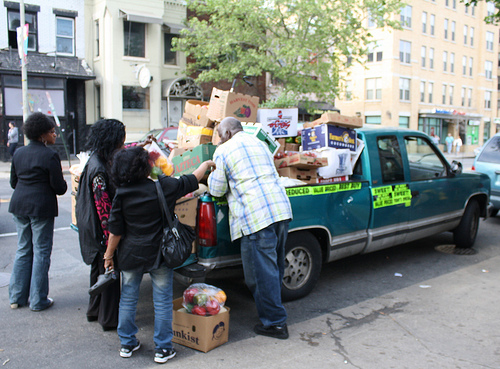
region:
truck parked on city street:
[15, 45, 486, 341]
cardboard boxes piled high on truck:
[142, 80, 357, 202]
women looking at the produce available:
[10, 100, 186, 355]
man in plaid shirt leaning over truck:
[190, 95, 310, 336]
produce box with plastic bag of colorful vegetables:
[160, 277, 235, 357]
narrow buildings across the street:
[0, 0, 330, 141]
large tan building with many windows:
[325, 10, 495, 150]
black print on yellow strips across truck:
[280, 175, 425, 207]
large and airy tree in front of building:
[161, 7, 383, 102]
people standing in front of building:
[415, 100, 483, 157]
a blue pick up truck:
[132, 97, 498, 281]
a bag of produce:
[172, 277, 238, 332]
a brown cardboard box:
[156, 293, 235, 353]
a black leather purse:
[152, 172, 207, 274]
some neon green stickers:
[369, 181, 419, 209]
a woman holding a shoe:
[91, 147, 217, 362]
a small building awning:
[159, 67, 212, 102]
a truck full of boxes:
[131, 77, 488, 217]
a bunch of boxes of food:
[163, 80, 335, 186]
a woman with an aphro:
[7, 106, 81, 322]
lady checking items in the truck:
[6, 111, 66, 311]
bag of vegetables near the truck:
[182, 282, 226, 313]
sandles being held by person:
[86, 257, 113, 294]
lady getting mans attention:
[100, 145, 217, 357]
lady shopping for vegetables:
[74, 118, 128, 332]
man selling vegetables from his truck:
[208, 116, 292, 340]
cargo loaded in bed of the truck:
[162, 85, 367, 189]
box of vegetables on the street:
[167, 290, 234, 350]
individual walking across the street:
[4, 120, 19, 159]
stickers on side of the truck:
[368, 180, 413, 210]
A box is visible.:
[195, 287, 239, 351]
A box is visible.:
[140, 265, 274, 359]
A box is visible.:
[187, 300, 271, 367]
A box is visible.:
[122, 251, 210, 366]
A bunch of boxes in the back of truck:
[92, 73, 407, 253]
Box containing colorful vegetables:
[156, 259, 239, 361]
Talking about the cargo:
[11, 78, 295, 264]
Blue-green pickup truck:
[103, 65, 493, 297]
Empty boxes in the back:
[150, 70, 368, 190]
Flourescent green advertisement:
[283, 181, 423, 222]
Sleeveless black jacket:
[71, 153, 138, 270]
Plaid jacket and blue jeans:
[186, 113, 318, 320]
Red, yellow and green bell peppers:
[172, 279, 244, 326]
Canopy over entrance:
[141, 61, 214, 137]